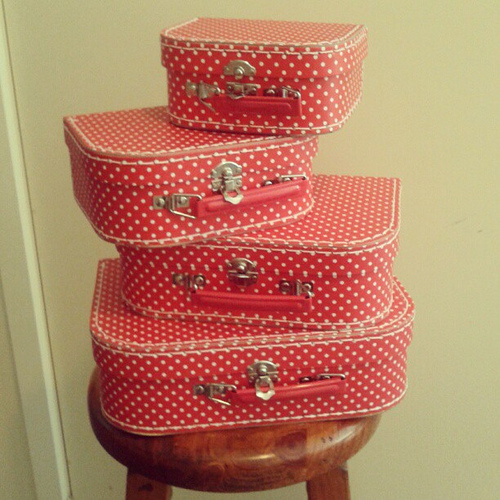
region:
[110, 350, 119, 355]
white dot on pink luggage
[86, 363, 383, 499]
wooden stool with small suitcase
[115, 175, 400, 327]
small dotted travel case with a pink handle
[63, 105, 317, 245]
small dotted case balanced on the edge of another case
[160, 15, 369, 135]
pink cosmetics travel case with white dots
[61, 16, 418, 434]
pile of four matching travel bags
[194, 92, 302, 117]
pink handle on a cosmetics case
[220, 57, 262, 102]
lock on a cosmetics travel case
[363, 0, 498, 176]
off-white wall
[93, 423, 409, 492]
edge of the seat of a wooden stool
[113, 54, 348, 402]
stack of red and white luggage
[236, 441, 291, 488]
brown wooden stool with bags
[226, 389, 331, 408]
red handle on large bag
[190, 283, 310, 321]
red handle on medium bag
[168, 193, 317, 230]
red handle on small bag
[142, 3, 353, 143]
tiny bag with white dots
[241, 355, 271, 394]
stainless lock on large bag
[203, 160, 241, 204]
stainless lock on small bag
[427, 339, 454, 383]
beige wall behind stool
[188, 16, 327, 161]
These are miniature red luggage pieces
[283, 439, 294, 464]
There is a dark wood stool here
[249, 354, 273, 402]
There is a silver luggage buckle here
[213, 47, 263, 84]
metal latch on luggage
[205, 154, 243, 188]
metal latch on luggage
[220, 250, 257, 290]
metal latch on luggage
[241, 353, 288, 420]
metal latch on luggage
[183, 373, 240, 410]
metal latch on luggage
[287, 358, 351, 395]
metal latch on luggage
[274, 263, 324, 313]
metal latch on luggage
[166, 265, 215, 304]
metal latch on luggage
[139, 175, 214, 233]
metal latch on luggage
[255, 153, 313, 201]
metal latch on luggage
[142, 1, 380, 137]
a polka dat designed box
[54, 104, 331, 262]
a polka dat designed box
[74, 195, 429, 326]
a polka dat designed box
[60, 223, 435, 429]
a polka dat designed box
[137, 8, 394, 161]
a polka dat designed box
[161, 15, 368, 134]
Red and white suitcase on the stool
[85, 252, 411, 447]
Red and white suitcase on the stool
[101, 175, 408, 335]
Red and white suitcase on the stool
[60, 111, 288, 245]
Red and white suitcase on the stool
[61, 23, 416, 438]
Red and white suitcases on the stool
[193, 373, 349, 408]
red handle on the suitcase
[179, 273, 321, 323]
red handle on the suitcase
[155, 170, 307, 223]
red handle on the suitcase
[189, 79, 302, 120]
red handle on the suitcase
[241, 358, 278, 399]
metal latch on the suitcase